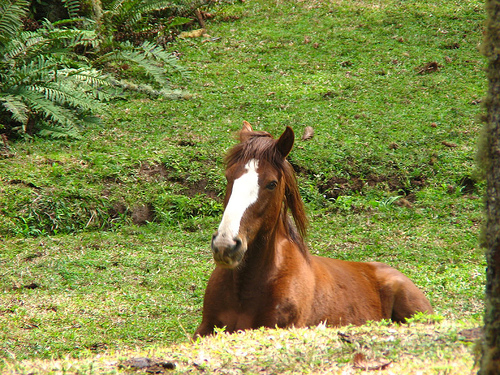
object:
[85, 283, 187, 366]
ditch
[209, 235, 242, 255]
nose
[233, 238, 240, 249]
nostrils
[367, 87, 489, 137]
grass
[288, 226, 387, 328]
torso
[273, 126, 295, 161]
ear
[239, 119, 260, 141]
ear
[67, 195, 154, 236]
mud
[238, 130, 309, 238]
mane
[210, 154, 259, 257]
spot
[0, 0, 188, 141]
ferns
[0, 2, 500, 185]
grassy hillside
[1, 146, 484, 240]
ditch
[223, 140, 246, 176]
mane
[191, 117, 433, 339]
horse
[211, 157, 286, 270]
face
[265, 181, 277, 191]
eye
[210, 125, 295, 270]
head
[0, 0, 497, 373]
field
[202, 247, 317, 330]
torso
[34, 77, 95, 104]
leaves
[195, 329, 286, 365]
grass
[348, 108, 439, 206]
spot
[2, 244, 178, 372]
grass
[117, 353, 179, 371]
rock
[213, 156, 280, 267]
face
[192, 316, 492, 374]
shadow